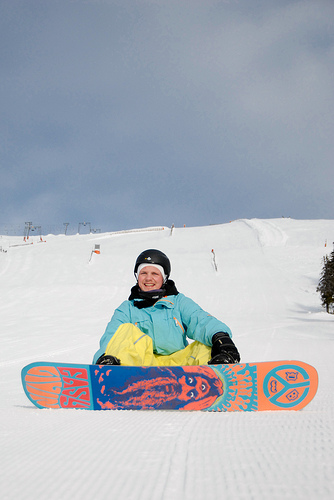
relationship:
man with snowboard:
[92, 247, 241, 364] [20, 362, 319, 412]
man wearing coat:
[92, 247, 241, 364] [96, 301, 230, 368]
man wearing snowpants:
[92, 247, 241, 364] [107, 322, 209, 366]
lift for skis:
[2, 218, 103, 240] [12, 242, 31, 248]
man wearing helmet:
[92, 247, 241, 364] [134, 249, 170, 275]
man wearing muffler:
[92, 247, 241, 364] [129, 285, 173, 306]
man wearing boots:
[92, 247, 241, 364] [98, 355, 121, 366]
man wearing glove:
[92, 247, 241, 364] [209, 333, 238, 365]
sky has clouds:
[1, 2, 333, 235] [162, 1, 333, 195]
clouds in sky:
[5, 123, 85, 235] [1, 2, 333, 235]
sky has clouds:
[1, 2, 333, 235] [5, 123, 85, 235]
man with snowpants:
[92, 247, 241, 364] [107, 322, 209, 366]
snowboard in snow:
[20, 362, 319, 412] [21, 230, 322, 473]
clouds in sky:
[5, 123, 85, 235] [7, 6, 323, 207]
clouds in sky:
[5, 14, 334, 216] [1, 2, 333, 235]